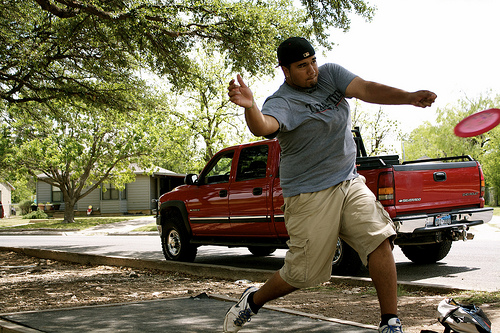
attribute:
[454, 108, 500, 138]
frisbee — red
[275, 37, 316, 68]
cap — black, dark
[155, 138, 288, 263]
truck — red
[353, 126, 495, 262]
truck — red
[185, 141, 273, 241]
door — double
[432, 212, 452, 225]
plate — license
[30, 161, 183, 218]
house — grey, white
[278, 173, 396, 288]
shorts — beige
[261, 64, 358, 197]
shirt — grey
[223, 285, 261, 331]
sneaker — white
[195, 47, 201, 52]
leaf — green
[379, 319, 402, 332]
shoe — black